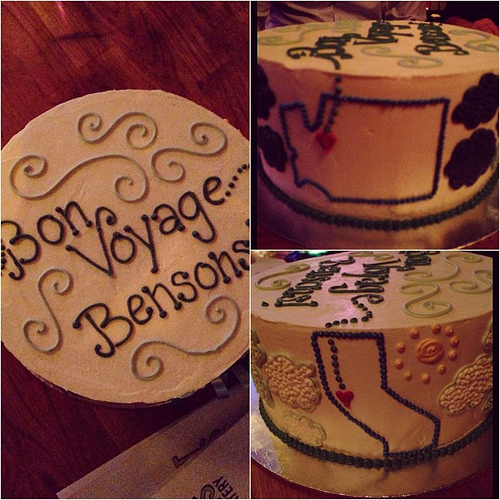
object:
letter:
[106, 230, 138, 265]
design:
[434, 352, 494, 416]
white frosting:
[0, 87, 252, 408]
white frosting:
[254, 21, 499, 221]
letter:
[59, 204, 119, 280]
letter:
[34, 208, 66, 249]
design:
[397, 281, 453, 320]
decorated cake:
[250, 250, 494, 472]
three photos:
[0, 0, 499, 498]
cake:
[0, 87, 250, 407]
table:
[0, 0, 250, 498]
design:
[397, 277, 455, 322]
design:
[360, 42, 445, 71]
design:
[70, 105, 161, 151]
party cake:
[255, 18, 499, 234]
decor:
[274, 407, 328, 450]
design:
[445, 267, 492, 298]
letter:
[71, 300, 137, 361]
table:
[6, 5, 243, 488]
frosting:
[252, 250, 492, 458]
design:
[391, 324, 458, 385]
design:
[20, 265, 74, 353]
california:
[307, 327, 442, 456]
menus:
[141, 415, 249, 499]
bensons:
[72, 240, 251, 360]